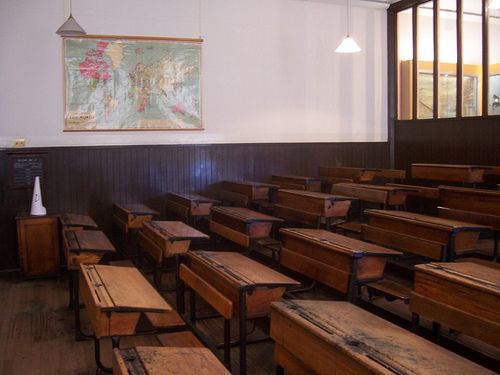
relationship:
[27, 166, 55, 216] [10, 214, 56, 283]
cone on table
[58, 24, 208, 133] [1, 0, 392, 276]
map on wall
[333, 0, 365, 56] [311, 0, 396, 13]
light hanging from ceiling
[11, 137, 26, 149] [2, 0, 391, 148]
switch on wall